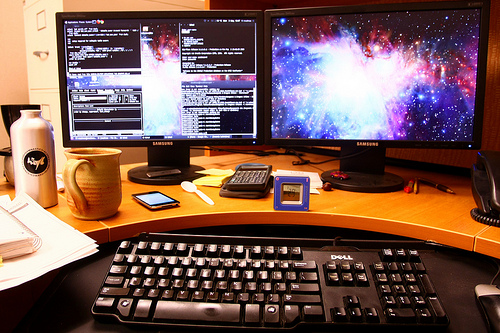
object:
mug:
[55, 140, 121, 219]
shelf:
[2, 224, 498, 331]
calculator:
[225, 162, 273, 189]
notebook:
[0, 202, 43, 258]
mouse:
[469, 277, 500, 332]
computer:
[50, 8, 264, 184]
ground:
[426, 139, 469, 152]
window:
[177, 17, 257, 79]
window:
[178, 75, 257, 136]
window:
[64, 17, 142, 71]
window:
[62, 85, 142, 131]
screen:
[260, 0, 484, 142]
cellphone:
[271, 174, 312, 213]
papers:
[0, 190, 105, 297]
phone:
[463, 148, 498, 228]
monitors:
[263, 0, 484, 152]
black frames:
[266, 1, 486, 148]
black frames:
[55, 9, 266, 148]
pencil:
[413, 175, 419, 193]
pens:
[403, 177, 414, 192]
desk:
[0, 138, 500, 333]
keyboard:
[87, 229, 453, 333]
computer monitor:
[264, 2, 492, 148]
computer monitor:
[55, 8, 264, 149]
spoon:
[180, 180, 214, 208]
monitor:
[61, 13, 253, 146]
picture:
[37, 10, 53, 29]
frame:
[33, 8, 47, 30]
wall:
[0, 4, 61, 190]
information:
[66, 17, 255, 149]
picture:
[276, 18, 479, 137]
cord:
[470, 206, 500, 229]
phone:
[130, 190, 181, 210]